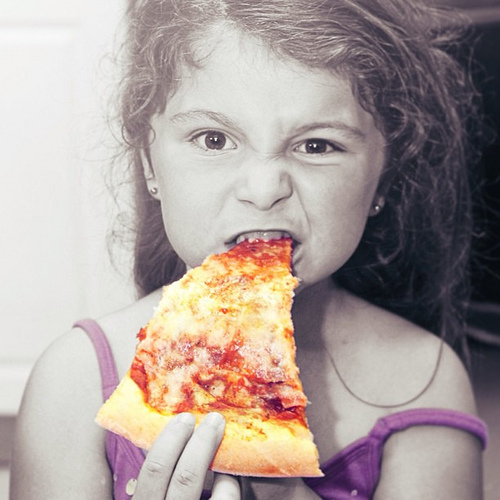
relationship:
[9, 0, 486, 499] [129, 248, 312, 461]
child eating pizza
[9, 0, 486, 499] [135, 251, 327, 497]
child biting pizza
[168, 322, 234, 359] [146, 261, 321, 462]
cheese on pizza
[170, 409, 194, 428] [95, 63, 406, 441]
fingernail on child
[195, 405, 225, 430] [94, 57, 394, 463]
fingernail on girl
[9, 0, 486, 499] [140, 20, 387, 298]
child has face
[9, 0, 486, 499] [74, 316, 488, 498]
child wearing dress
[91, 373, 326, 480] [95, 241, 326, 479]
crust on pizza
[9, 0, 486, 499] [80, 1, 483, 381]
child has hair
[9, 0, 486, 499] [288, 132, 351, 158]
child has eye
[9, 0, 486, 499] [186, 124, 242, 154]
child has eye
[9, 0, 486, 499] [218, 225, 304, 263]
child has mouth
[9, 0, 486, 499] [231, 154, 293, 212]
child has nose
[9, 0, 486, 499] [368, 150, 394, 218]
child has ear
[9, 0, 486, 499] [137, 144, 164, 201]
child has ear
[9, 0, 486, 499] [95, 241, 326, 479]
child holding pizza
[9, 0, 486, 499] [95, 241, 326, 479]
child eating pizza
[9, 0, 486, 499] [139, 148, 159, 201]
child has ear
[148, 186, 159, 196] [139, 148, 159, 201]
earring in ear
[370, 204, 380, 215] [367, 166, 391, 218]
earring in ear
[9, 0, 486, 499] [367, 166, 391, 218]
child has ear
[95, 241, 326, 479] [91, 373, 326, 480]
pizza has crust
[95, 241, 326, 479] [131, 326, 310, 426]
pizza has sauce